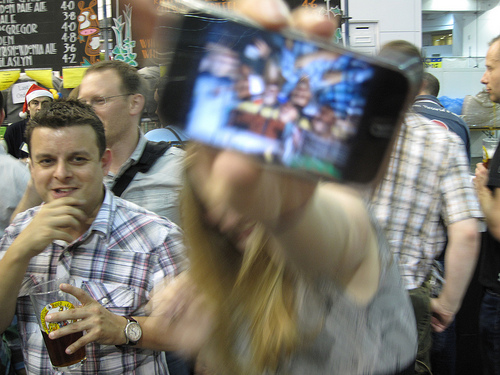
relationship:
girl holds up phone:
[151, 140, 419, 373] [146, 4, 415, 190]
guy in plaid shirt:
[7, 100, 194, 373] [3, 182, 190, 374]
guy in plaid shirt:
[337, 40, 487, 373] [368, 110, 487, 293]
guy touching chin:
[7, 100, 194, 373] [48, 197, 83, 209]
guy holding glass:
[0, 100, 193, 375] [23, 280, 97, 362]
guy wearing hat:
[0, 100, 193, 375] [17, 82, 56, 122]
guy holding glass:
[468, 31, 498, 371] [477, 132, 499, 167]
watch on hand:
[115, 315, 143, 350] [39, 271, 141, 358]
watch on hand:
[115, 315, 143, 350] [46, 277, 128, 352]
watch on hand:
[115, 315, 143, 350] [29, 262, 181, 367]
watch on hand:
[121, 310, 148, 361] [57, 280, 97, 366]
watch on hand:
[115, 315, 143, 350] [32, 193, 93, 244]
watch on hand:
[115, 315, 143, 350] [32, 278, 87, 368]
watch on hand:
[115, 315, 143, 350] [44, 284, 127, 355]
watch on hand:
[115, 315, 143, 350] [42, 275, 146, 358]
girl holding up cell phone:
[151, 140, 419, 373] [156, 10, 411, 185]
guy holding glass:
[0, 100, 193, 375] [20, 274, 102, 372]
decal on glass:
[36, 297, 80, 340] [26, 273, 91, 371]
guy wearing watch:
[0, 100, 193, 375] [116, 316, 143, 351]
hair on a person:
[161, 130, 357, 336] [147, 1, 423, 372]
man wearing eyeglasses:
[75, 60, 188, 228] [75, 95, 111, 110]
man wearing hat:
[0, 61, 55, 178] [19, 82, 56, 120]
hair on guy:
[34, 100, 94, 129] [337, 40, 488, 375]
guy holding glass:
[337, 40, 488, 375] [19, 276, 110, 374]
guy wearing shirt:
[337, 40, 488, 375] [2, 181, 192, 371]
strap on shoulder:
[107, 140, 169, 195] [138, 138, 188, 188]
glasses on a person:
[84, 89, 161, 115] [11, 53, 188, 226]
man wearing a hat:
[5, 83, 55, 158] [15, 73, 80, 114]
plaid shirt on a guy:
[368, 110, 487, 293] [337, 40, 488, 375]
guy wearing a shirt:
[337, 40, 488, 375] [2, 181, 192, 371]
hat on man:
[13, 79, 51, 111] [4, 80, 60, 159]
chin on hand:
[45, 195, 87, 229] [20, 195, 91, 252]